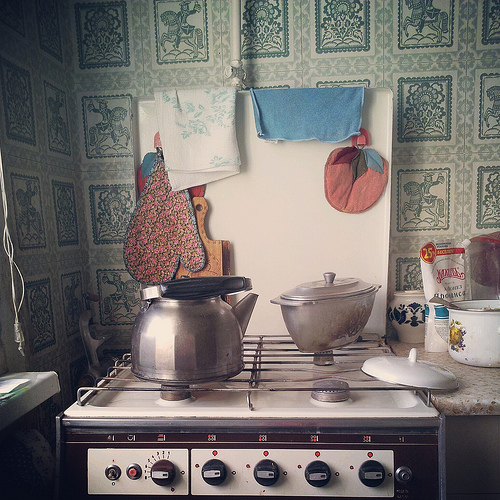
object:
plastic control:
[1, 189, 38, 355]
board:
[138, 88, 396, 340]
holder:
[324, 126, 391, 216]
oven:
[54, 362, 449, 499]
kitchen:
[0, 1, 499, 496]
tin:
[385, 288, 427, 345]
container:
[270, 271, 383, 353]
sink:
[0, 368, 60, 429]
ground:
[388, 136, 456, 171]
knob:
[201, 460, 228, 486]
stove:
[54, 333, 446, 500]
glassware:
[269, 269, 382, 350]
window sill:
[2, 370, 65, 428]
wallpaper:
[386, 25, 476, 156]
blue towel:
[248, 86, 367, 141]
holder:
[123, 152, 207, 285]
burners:
[309, 378, 349, 403]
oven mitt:
[121, 141, 205, 288]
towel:
[153, 89, 241, 191]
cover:
[359, 347, 460, 391]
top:
[360, 346, 459, 391]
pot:
[445, 299, 500, 370]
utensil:
[427, 296, 458, 310]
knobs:
[358, 459, 386, 487]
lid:
[278, 272, 374, 300]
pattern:
[388, 301, 423, 327]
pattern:
[241, 0, 378, 68]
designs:
[323, 128, 390, 214]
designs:
[330, 134, 385, 184]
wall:
[66, 73, 466, 331]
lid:
[150, 274, 220, 299]